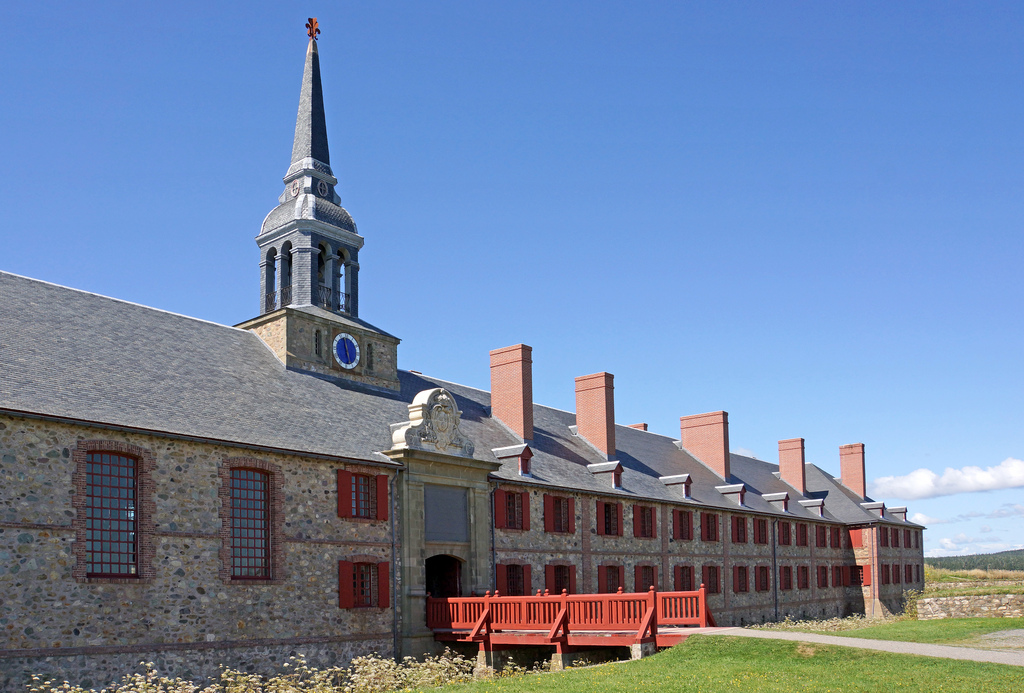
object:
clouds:
[876, 451, 1023, 508]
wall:
[911, 593, 1021, 625]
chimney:
[570, 370, 616, 454]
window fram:
[332, 467, 391, 522]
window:
[65, 437, 149, 582]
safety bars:
[83, 456, 137, 580]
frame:
[217, 453, 282, 587]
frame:
[338, 555, 388, 606]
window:
[337, 557, 390, 612]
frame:
[65, 442, 154, 587]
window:
[493, 483, 533, 534]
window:
[491, 559, 530, 595]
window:
[545, 561, 577, 598]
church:
[0, 17, 924, 690]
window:
[592, 501, 624, 535]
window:
[594, 557, 626, 597]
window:
[628, 509, 660, 537]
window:
[632, 557, 659, 600]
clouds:
[919, 506, 1020, 539]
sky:
[2, 2, 1021, 551]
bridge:
[425, 580, 710, 660]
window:
[336, 469, 389, 523]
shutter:
[332, 469, 350, 521]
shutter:
[370, 476, 389, 521]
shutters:
[518, 487, 531, 534]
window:
[349, 562, 381, 610]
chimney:
[483, 343, 540, 442]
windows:
[217, 454, 282, 585]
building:
[0, 263, 922, 688]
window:
[543, 560, 575, 603]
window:
[695, 511, 722, 548]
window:
[485, 491, 530, 532]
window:
[543, 497, 576, 536]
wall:
[0, 402, 414, 680]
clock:
[329, 328, 361, 371]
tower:
[247, 13, 370, 361]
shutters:
[666, 508, 685, 546]